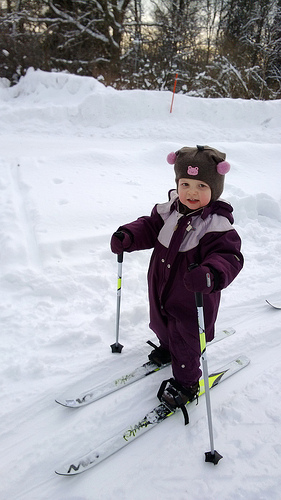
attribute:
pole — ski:
[110, 252, 124, 355]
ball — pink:
[219, 160, 230, 177]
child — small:
[108, 140, 247, 413]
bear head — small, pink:
[187, 165, 198, 175]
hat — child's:
[171, 144, 228, 201]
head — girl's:
[149, 141, 246, 219]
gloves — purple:
[102, 215, 171, 280]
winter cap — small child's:
[165, 145, 228, 200]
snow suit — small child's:
[109, 200, 245, 389]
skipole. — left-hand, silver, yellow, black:
[185, 257, 223, 459]